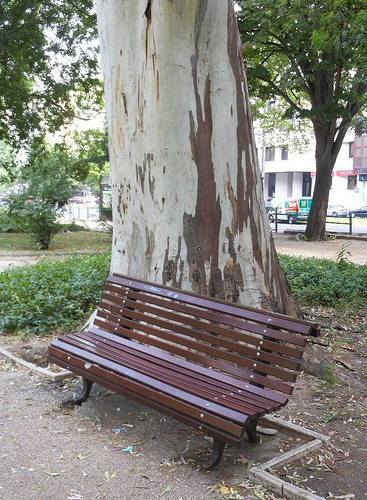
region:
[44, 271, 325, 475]
a brown bench in a park.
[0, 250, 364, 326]
grass around a tree near a bench.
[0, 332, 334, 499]
a brick garden boarder around a tree.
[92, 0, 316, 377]
a tree near a bench.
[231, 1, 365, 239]
a tree with lots of leaves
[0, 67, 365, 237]
a row of building.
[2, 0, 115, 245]
a bunch of green leafs.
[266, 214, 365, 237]
a road near buildings.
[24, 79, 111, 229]
a tall building near a park.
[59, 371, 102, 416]
a black metal bar.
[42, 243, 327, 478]
bench under the large tree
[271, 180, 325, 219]
van on the street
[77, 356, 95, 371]
bench is missing a piece of wood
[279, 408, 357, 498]
leaves on the ground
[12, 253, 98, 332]
greenery around the tree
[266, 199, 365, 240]
fence in front of tree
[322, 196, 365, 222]
cars parked on the road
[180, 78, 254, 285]
bark missing from tree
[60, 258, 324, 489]
bench is empty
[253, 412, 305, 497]
trim around the ground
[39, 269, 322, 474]
Shiny brown bench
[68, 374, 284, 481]
Black legs on brown bench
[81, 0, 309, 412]
brown and white tree trunk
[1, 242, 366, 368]
Area of green grass around the tree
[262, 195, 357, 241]
Black fence around the sidewalk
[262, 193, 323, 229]
Red white and blue van on the curb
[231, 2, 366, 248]
Tall green tree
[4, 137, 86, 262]
Tall green bush in the background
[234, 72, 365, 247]
White building in the distance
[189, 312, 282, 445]
White bolts on brown bench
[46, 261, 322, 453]
one bench is visible.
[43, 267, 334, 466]
the bench is brown.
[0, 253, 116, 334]
the grass is green.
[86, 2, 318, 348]
large tree trunk behind the bench.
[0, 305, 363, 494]
leaves on the ground.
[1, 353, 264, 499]
the ground is brown.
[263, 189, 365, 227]
cars on the street.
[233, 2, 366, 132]
the leaves are green.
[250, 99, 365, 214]
the building is white.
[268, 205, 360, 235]
fence in the background.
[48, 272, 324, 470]
a brown bench by a big tree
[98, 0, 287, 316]
a trunk of a tree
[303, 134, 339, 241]
a trunk of a tree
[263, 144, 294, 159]
the windows of a building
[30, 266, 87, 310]
the leaves of plants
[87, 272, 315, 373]
the back of a brown bench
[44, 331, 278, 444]
the seat of a brown bench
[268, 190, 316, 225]
a van parked in front of a building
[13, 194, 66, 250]
a bush on the side of a walkway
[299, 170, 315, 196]
a window of a building